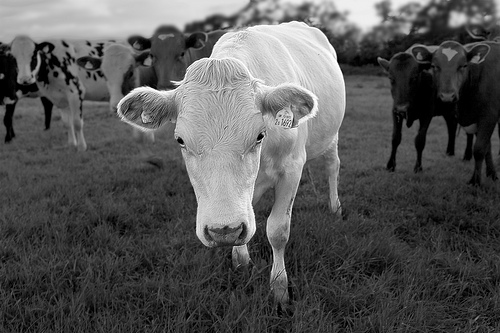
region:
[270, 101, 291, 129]
small identification tag in the cows left ear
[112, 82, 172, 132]
blonde cow's left ear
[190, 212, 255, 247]
blonde cow's snout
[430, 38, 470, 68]
black forehead with a white Texas shaped patch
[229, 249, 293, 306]
blonde cow's two front hooves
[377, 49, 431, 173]
front end of a young bull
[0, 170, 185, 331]
nice big patch of plush grass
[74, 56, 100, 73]
black cow's ear with a white patch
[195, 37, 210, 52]
older metal version of the plastic tags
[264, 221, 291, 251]
blonde cow's knobby knee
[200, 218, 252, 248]
young cow has cow nose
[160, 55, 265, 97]
young cow has somewhere between moptop & emo haircut [but may be unaware of this fact]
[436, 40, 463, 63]
equally yong cow is dark w/ light blaze on face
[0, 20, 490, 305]
cows' ears perpendicular to cows' heads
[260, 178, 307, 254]
cow has knobby foreleg knee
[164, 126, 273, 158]
cow has dark, inquisitive, sad eyes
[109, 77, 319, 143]
main cow has finely fur-fuzzy ears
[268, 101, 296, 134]
cow has unfortunate tag in left ear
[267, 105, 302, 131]
tag is hard to read but says, at least, '2__692' w/ something illegible on top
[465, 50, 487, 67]
dark cow to left also has visible, unintelligible tag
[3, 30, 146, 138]
spotted cow in a field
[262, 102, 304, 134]
identifying tag on the cows ear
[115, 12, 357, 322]
white cow in the field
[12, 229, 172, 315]
long healthy field of grass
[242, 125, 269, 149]
eye of a cow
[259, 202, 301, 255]
joint of a cows leg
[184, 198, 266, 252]
snout of a cow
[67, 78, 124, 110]
belly of a spotted cow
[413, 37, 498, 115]
white patch on a brown cow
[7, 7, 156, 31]
gray sky with clouds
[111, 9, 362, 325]
a white cow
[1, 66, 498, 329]
a grassy field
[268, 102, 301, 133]
a white tag in a cow's ear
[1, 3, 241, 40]
a cloudy sky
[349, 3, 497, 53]
trees behind the cows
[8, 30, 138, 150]
a black and white spotted cow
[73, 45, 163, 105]
a white face on a brown cow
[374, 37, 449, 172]
a brown cow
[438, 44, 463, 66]
a white spot on a brown cow's head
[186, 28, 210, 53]
a brown cow ear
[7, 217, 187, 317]
section of thick grass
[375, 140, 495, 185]
animal hooves on a field of grass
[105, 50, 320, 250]
face of a white cow staring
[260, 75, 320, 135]
tagged ear of a cow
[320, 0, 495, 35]
out-of-focus trees in the distance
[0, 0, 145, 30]
a cloudy sky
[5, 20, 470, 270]
a small herd of domestic animals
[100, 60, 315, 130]
two tagged ears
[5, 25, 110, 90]
white spotted cow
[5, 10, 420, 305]
black and white photo of cows